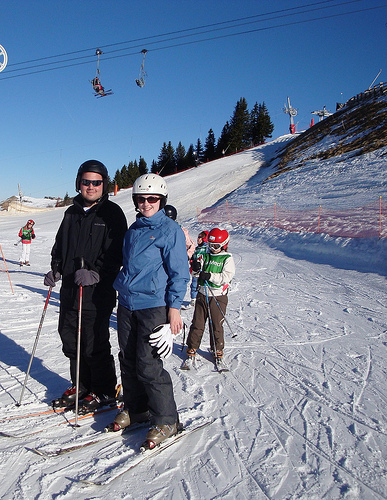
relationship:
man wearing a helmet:
[39, 157, 127, 412] [75, 163, 113, 200]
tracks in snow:
[6, 258, 385, 498] [3, 126, 383, 499]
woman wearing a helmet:
[116, 169, 190, 449] [75, 163, 113, 200]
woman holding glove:
[116, 169, 190, 449] [141, 326, 175, 358]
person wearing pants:
[16, 218, 35, 265] [19, 236, 37, 272]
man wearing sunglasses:
[39, 157, 127, 412] [75, 177, 103, 195]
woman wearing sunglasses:
[116, 169, 190, 449] [130, 195, 159, 209]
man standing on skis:
[39, 157, 127, 412] [3, 407, 73, 440]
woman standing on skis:
[116, 169, 190, 449] [27, 410, 202, 483]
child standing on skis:
[176, 223, 238, 366] [176, 355, 232, 381]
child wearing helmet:
[176, 223, 238, 366] [202, 225, 228, 246]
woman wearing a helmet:
[116, 169, 190, 449] [130, 169, 170, 202]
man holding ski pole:
[39, 157, 127, 412] [65, 253, 86, 431]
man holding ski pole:
[39, 157, 127, 412] [13, 272, 57, 412]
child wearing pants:
[176, 223, 238, 366] [185, 291, 228, 357]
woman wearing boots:
[116, 169, 190, 449] [107, 410, 180, 450]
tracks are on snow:
[6, 258, 385, 498] [3, 126, 383, 499]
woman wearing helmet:
[116, 169, 190, 449] [130, 169, 170, 202]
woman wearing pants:
[116, 169, 190, 449] [119, 296, 181, 430]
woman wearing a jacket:
[116, 169, 190, 449] [118, 210, 190, 319]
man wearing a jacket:
[39, 157, 127, 412] [45, 202, 124, 282]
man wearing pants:
[39, 157, 127, 412] [54, 283, 120, 401]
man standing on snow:
[39, 157, 127, 412] [3, 126, 383, 499]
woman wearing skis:
[116, 169, 190, 449] [27, 410, 202, 483]